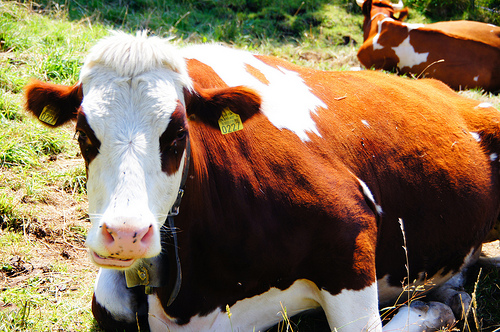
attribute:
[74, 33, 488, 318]
cow — brown, laying down, large, white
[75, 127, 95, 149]
eye — dark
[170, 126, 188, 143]
eye — brown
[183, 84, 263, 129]
ear — brown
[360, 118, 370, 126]
spot — white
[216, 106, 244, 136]
tag — yellow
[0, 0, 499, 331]
grass — green, brown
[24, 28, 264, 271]
head — white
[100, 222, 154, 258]
nose — pink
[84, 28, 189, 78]
fur — white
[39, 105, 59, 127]
tag — yellow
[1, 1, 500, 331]
hill — green